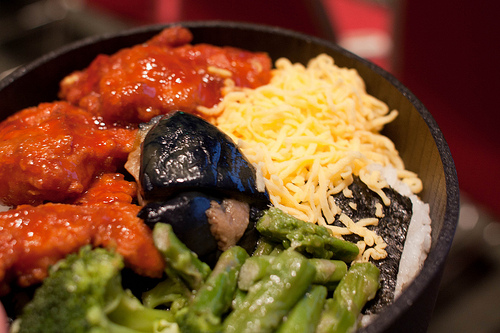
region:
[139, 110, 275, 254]
This is a piece of food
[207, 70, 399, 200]
This is a piece of food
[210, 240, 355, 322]
This is a piece of food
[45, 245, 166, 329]
This is a piece of food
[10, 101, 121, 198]
This is a piece of food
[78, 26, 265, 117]
This is a piece of food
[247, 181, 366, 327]
This is a piece of food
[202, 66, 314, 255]
a yellow grated cheese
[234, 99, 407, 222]
a yellow grated cheese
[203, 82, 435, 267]
a yellow grated cheese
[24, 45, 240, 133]
red sauce on the chicken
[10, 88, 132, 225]
red sauce on the chicken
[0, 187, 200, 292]
red sauce on the chicken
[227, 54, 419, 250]
cheese sprinkled at the side of the dish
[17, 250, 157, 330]
a piece of broccoli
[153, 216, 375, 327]
green beans next to broccoli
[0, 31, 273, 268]
chicken in red sauce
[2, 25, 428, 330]
complete meal in dish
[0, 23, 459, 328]
black, deep dish with food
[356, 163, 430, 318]
portion of white rice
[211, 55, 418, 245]
cheddar cheese sprinlked to the side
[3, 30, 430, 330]
meal in a black bowl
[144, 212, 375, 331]
greens at one side of bowl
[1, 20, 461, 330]
The bowl is wooden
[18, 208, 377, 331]
The vegetables are green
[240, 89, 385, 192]
The cheese is orange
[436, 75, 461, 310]
The rim of the bowl is black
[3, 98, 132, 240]
The food is reddish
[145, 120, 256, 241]
The middle food is black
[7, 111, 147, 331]
The orange food is next to the vegetables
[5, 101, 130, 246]
The food is orange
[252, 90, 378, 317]
The cheese is touching the vegetables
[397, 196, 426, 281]
The rice is white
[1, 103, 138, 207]
A chicken wing smuthered in sauce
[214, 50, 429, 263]
Yellow shredded cheese on side of dish.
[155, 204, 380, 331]
Cooked, chopped green asparagus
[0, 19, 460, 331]
A wooden bowl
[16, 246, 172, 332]
A peice of brocoli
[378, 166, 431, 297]
White cooked sticky rice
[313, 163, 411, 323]
A peice of seaweed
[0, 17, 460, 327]
cooked food in a bowl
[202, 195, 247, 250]
brown sauce or gravy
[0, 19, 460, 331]
A wooden dish with food in it.